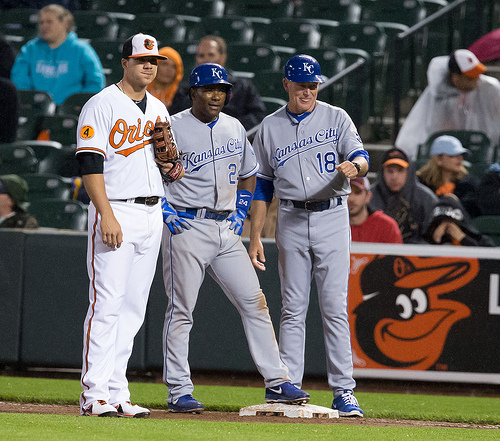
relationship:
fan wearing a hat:
[393, 45, 498, 159] [444, 48, 489, 81]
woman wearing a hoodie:
[7, 6, 105, 96] [11, 40, 104, 102]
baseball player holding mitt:
[68, 32, 184, 418] [153, 121, 181, 179]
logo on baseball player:
[111, 116, 167, 155] [68, 32, 184, 418]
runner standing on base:
[165, 63, 310, 411] [232, 396, 342, 423]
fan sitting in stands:
[393, 45, 498, 159] [1, 2, 500, 264]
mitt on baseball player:
[153, 121, 181, 179] [68, 32, 184, 418]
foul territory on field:
[1, 369, 499, 416] [1, 367, 500, 441]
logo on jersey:
[111, 116, 167, 155] [74, 87, 172, 201]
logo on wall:
[344, 254, 498, 374] [2, 229, 499, 388]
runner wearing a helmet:
[165, 63, 310, 411] [190, 61, 236, 89]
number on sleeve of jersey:
[78, 123, 95, 140] [74, 87, 172, 201]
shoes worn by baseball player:
[78, 397, 152, 417] [68, 32, 184, 418]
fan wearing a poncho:
[393, 45, 498, 159] [389, 49, 500, 157]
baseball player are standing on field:
[74, 32, 183, 418] [1, 367, 500, 441]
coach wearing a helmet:
[246, 48, 365, 421] [286, 54, 326, 85]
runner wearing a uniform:
[165, 63, 310, 411] [152, 109, 287, 399]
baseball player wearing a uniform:
[68, 32, 184, 418] [75, 82, 174, 404]